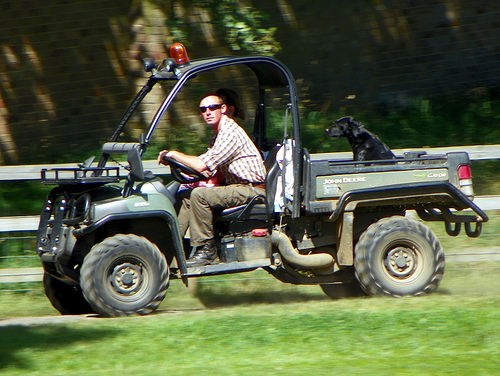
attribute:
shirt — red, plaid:
[203, 125, 248, 214]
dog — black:
[317, 102, 401, 172]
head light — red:
[456, 161, 471, 179]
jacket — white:
[263, 148, 321, 213]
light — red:
[168, 40, 189, 64]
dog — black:
[320, 117, 397, 170]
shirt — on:
[226, 137, 257, 174]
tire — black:
[77, 231, 175, 323]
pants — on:
[171, 181, 271, 265]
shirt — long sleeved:
[208, 125, 265, 193]